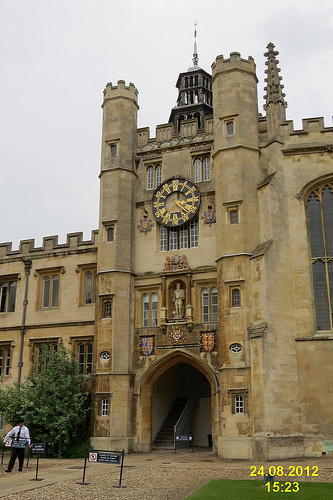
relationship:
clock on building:
[149, 173, 204, 227] [72, 210, 328, 358]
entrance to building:
[129, 340, 235, 467] [0, 30, 329, 460]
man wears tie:
[4, 412, 43, 482] [16, 424, 23, 437]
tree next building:
[1, 337, 91, 458] [0, 30, 329, 460]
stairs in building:
[146, 389, 201, 450] [0, 30, 329, 460]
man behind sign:
[2, 421, 31, 468] [1, 436, 29, 465]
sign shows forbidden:
[85, 449, 120, 464] [86, 449, 126, 463]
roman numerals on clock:
[148, 172, 203, 228] [146, 176, 229, 232]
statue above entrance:
[174, 284, 184, 317] [136, 348, 218, 455]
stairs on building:
[153, 397, 191, 450] [110, 102, 301, 489]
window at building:
[227, 388, 246, 417] [0, 30, 329, 460]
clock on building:
[151, 174, 200, 225] [71, 56, 322, 476]